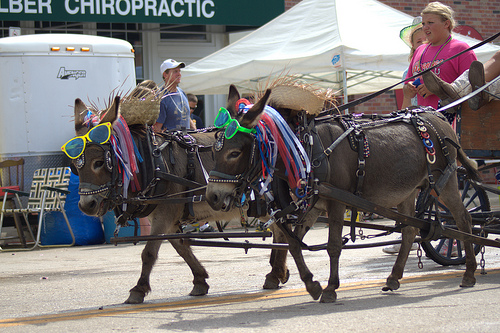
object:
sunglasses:
[212, 106, 257, 140]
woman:
[402, 0, 476, 129]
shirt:
[402, 34, 478, 129]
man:
[150, 57, 192, 133]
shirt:
[154, 85, 191, 130]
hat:
[160, 57, 187, 76]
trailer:
[0, 33, 140, 210]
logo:
[54, 66, 87, 79]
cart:
[63, 29, 499, 305]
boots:
[419, 70, 472, 115]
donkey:
[129, 79, 161, 100]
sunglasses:
[59, 121, 112, 161]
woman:
[397, 15, 430, 110]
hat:
[398, 15, 423, 49]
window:
[124, 30, 142, 48]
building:
[0, 0, 287, 138]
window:
[110, 29, 128, 42]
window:
[94, 30, 115, 38]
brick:
[362, 101, 372, 105]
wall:
[354, 0, 499, 115]